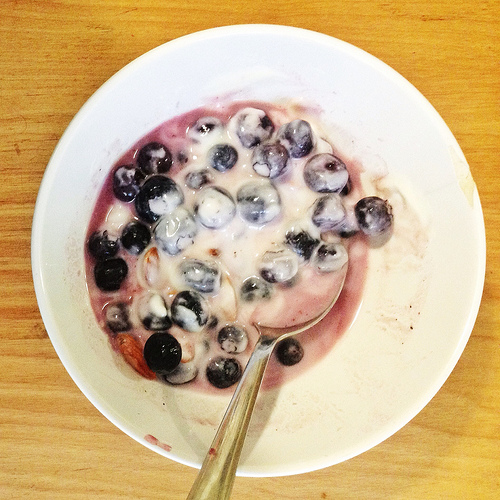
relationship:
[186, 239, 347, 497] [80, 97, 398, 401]
spoon scoops dessert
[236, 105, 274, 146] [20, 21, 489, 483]
berry on bowl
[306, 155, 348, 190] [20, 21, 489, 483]
blueberry on bowl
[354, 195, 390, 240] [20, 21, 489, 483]
blueberry on bowl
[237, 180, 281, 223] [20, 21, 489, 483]
blueberry on bowl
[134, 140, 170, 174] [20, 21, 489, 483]
blueberry on bowl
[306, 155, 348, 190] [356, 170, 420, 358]
blueberry with cream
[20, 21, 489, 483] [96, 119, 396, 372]
bowl of food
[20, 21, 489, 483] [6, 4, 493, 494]
bowl on table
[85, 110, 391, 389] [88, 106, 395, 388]
bunch of blueberry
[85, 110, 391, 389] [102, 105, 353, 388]
bunch of cream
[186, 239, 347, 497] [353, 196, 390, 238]
spoon dipped in fruit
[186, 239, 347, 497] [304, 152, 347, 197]
spoon dipped in fruit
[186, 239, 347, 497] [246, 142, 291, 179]
spoon dipped in fruit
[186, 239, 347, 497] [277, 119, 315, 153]
spoon dipped in fruit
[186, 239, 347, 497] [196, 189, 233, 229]
spoon dipped in fruit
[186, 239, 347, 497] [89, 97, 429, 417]
spoon dipped in cream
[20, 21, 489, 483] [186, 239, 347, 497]
bowl with spoon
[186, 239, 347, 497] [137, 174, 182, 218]
spoon dipped in blueberry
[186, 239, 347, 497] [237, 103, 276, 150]
spoon dipped in blueberry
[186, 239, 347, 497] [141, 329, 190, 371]
spoon dipped in blueberry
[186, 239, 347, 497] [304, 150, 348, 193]
spoon dipped in blueberry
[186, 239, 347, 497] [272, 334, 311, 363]
spoon dipped in blueberry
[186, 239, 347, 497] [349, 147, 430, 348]
spoon dipped in cream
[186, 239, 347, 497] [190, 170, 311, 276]
spoon dipped in cream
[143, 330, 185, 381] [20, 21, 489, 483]
berry in bowl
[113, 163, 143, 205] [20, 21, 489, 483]
berry in bowl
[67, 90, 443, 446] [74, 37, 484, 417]
dessert in bowl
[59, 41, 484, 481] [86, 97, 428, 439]
bowl for serving dessert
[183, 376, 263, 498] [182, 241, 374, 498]
part of spoon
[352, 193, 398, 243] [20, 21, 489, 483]
berry in bowl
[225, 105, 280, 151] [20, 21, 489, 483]
berry in bowl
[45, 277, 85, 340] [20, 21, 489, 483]
part of bowl